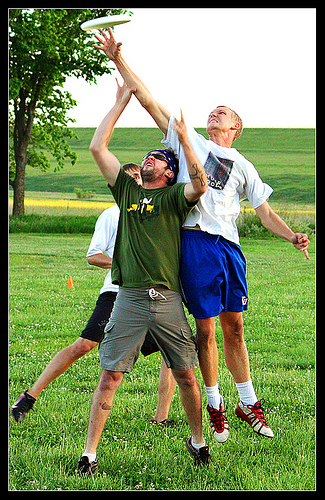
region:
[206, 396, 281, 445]
a pair of red and white cleats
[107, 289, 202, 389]
a pair of grey shorts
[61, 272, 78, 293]
a orange field cone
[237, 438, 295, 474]
a field of green grass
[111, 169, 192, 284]
a green tee shirt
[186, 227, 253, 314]
a pair of blue shorts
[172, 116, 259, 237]
a white tee shirt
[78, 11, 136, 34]
a white frisbie in the air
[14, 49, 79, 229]
a tree growing on the left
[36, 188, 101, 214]
yellow flowers growing in the field.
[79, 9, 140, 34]
yellow frisbee in air above men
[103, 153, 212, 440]
man in green shirt reaching for frisbee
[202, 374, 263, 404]
tall white socks on man on right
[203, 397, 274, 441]
red and white athletic shoes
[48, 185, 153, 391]
man in white behind other men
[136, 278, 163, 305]
white lace knot on pants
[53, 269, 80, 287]
small orange cone in grass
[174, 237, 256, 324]
blue shorts on man on right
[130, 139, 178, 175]
sunglasses on man in green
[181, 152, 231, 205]
cross tattoo on man in green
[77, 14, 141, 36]
White frisbee in iar.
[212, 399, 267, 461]
Person wearing red and white shoes.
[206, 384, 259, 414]
Person wearing white socks.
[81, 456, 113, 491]
Person wearing dark shoes.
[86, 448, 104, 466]
Person wearing white socks.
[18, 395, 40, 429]
Person wearing black shoes.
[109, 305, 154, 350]
Person wearing gray shorts.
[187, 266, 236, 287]
Person wearing blue shorts.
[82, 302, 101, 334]
Person wearing black shorts.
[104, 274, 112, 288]
Person wearing white shirt.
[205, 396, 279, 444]
Red cleats with black laces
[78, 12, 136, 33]
Frisby flying through the air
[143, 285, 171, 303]
Drawstring on a pair of shorts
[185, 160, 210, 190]
Tattoo on forearm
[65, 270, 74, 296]
Traffic cone sitting in the grass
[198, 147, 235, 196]
Design printed on T-shirts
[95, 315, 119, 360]
Side pocket of cargo shorts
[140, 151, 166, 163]
Sunglasses worn by frisbee player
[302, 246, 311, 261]
Extended pinky finger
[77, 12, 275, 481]
Men trying to catch a frisbee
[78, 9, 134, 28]
white frisbee in mid air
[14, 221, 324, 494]
field of green grass and small flowers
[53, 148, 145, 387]
man in white shirt behind other men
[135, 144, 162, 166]
sunglasses on face of man in green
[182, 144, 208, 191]
cross tattoo on man in greeb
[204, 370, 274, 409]
tall white socks on man on left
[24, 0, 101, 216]
tall tree in the background on left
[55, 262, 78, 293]
orange cone amid green field